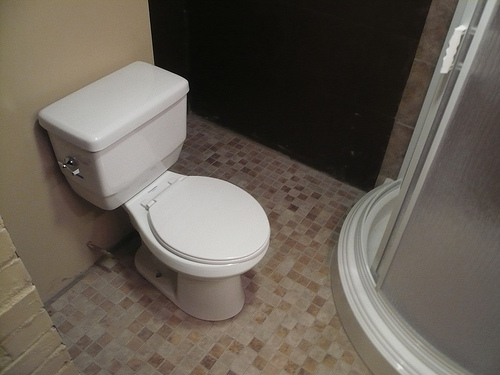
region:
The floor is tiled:
[39, 77, 379, 373]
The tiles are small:
[51, 97, 368, 372]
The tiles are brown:
[39, 102, 367, 371]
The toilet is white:
[43, 60, 270, 322]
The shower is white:
[333, 4, 495, 373]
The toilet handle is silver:
[53, 148, 84, 180]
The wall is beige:
[1, 3, 153, 373]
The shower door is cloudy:
[372, 19, 496, 369]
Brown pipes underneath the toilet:
[81, 226, 141, 277]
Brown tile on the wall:
[361, 2, 457, 212]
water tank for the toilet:
[38, 62, 190, 202]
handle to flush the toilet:
[58, 154, 88, 181]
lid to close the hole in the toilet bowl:
[146, 174, 272, 256]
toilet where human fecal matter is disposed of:
[34, 59, 271, 318]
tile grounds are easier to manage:
[75, 312, 187, 369]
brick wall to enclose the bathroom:
[0, 217, 77, 372]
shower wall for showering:
[386, 5, 494, 353]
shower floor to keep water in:
[336, 171, 384, 366]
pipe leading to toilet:
[89, 236, 140, 270]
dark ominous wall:
[186, 10, 365, 75]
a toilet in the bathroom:
[30, 45, 282, 331]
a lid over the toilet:
[129, 169, 277, 324]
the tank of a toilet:
[36, 48, 201, 214]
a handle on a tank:
[51, 146, 87, 183]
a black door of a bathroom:
[151, 2, 433, 202]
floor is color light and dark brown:
[61, 147, 347, 372]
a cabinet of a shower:
[331, 6, 498, 370]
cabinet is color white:
[328, 0, 498, 371]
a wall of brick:
[1, 218, 85, 370]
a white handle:
[423, 15, 485, 100]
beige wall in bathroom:
[0, 1, 154, 303]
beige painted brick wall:
[0, 217, 80, 372]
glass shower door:
[368, 1, 498, 373]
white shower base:
[326, 173, 476, 373]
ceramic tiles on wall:
[369, 2, 457, 189]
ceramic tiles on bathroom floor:
[39, 110, 374, 374]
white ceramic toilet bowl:
[123, 166, 273, 321]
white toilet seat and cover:
[138, 173, 271, 263]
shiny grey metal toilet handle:
[53, 155, 80, 175]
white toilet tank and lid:
[36, 60, 190, 212]